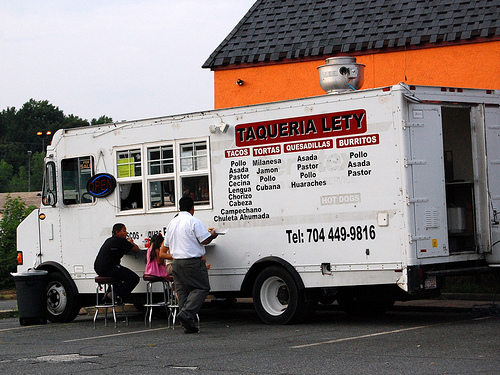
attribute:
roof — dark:
[209, 2, 494, 74]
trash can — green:
[9, 269, 50, 324]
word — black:
[346, 148, 366, 158]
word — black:
[346, 158, 370, 166]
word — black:
[345, 168, 372, 176]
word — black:
[288, 179, 326, 189]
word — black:
[254, 182, 281, 192]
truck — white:
[9, 81, 497, 302]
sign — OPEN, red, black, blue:
[83, 172, 118, 198]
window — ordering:
[180, 140, 210, 206]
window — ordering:
[146, 145, 179, 210]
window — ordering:
[115, 144, 150, 214]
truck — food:
[4, 46, 498, 331]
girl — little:
[134, 231, 191, 296]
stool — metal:
[87, 270, 134, 327]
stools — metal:
[89, 276, 204, 333]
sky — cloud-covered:
[0, 2, 256, 121]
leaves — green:
[3, 97, 112, 269]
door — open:
[407, 103, 490, 258]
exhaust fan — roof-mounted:
[315, 55, 367, 92]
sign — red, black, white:
[231, 118, 368, 143]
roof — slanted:
[200, 0, 498, 71]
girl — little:
[141, 224, 172, 276]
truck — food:
[15, 77, 497, 329]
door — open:
[457, 102, 497, 255]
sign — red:
[230, 108, 371, 149]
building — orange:
[199, 1, 499, 114]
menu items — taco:
[221, 144, 253, 207]